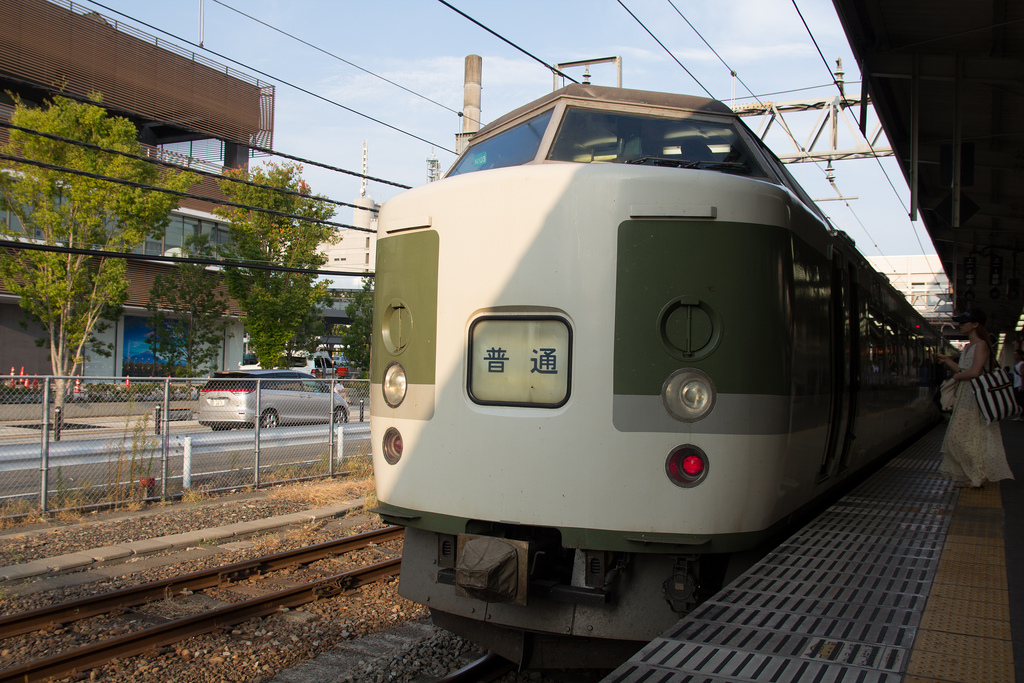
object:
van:
[198, 370, 351, 432]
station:
[580, 0, 1018, 683]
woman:
[933, 310, 1016, 490]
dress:
[939, 338, 1019, 485]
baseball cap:
[953, 305, 987, 329]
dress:
[940, 333, 1012, 486]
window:
[544, 104, 773, 183]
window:
[444, 105, 557, 180]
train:
[366, 83, 969, 680]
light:
[665, 368, 715, 423]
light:
[664, 444, 710, 490]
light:
[382, 362, 407, 408]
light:
[382, 426, 404, 466]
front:
[372, 85, 791, 553]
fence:
[0, 376, 373, 522]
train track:
[0, 525, 408, 683]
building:
[0, 0, 276, 418]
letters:
[465, 304, 573, 411]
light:
[676, 453, 710, 482]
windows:
[440, 96, 774, 186]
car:
[200, 370, 352, 432]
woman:
[928, 324, 1012, 446]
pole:
[183, 437, 192, 499]